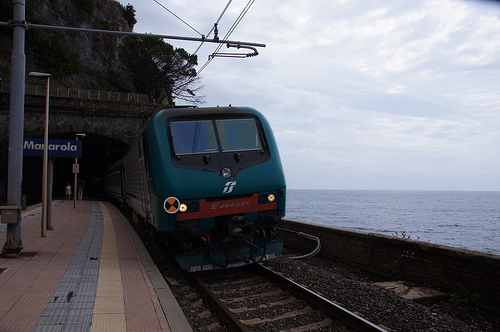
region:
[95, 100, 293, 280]
A train pulling into a train station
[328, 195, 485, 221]
ocean to the side of the train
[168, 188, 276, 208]
lights on the front of the train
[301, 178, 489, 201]
horizon line in the distance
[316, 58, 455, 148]
sky is full with clouds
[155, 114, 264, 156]
windshield on the train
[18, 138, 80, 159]
sign on the platform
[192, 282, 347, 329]
train tracks by the ocean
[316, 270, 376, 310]
gravel by the train tracks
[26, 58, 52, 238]
light post on the platform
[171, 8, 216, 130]
wires above the trian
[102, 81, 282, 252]
light rail car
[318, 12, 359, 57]
white clouds in blue sky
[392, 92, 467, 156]
white clouds in blue sky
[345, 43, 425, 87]
white clouds in blue sky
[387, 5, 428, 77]
white clouds in blue sky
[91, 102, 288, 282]
Train pulling into a train station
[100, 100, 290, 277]
Train pulling into a train station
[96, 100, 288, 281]
Train pulling into a train station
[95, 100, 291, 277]
Train pulling into a train station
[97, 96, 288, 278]
Train pulling into a train station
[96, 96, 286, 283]
Train pulling into a train station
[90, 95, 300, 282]
Train pulling into a train station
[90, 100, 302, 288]
Train pulling into a train station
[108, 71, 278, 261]
light rail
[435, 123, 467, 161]
white and blue ocean waves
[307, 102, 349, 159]
white and blue ocean waves